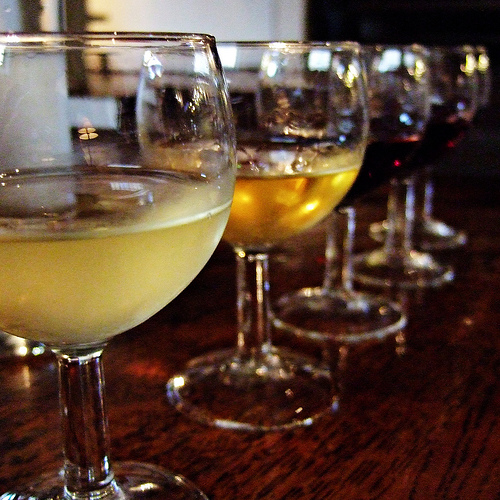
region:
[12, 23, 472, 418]
a bunch of wine glasses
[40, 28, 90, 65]
the rim of a wine glass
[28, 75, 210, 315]
the cup of a wine glass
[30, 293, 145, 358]
the base of a wine glass cup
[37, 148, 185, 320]
a bunch of light yellow wine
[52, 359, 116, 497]
the stem of a wine glass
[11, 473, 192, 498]
the base of a wine glass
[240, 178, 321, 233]
a dark yellow wine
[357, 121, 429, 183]
a dark purple wine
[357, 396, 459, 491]
a dark brown wooden tabletop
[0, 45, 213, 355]
wine glass filled with liquid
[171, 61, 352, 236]
wine glass filled with liquid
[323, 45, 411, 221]
wine glass filled with liquid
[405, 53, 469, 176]
wine glass filled with liquid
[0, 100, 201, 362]
glass is half full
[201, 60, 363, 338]
glass is half full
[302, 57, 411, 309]
glass is half full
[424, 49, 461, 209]
glass is half full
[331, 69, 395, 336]
glass of red wine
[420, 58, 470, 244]
glass of red wine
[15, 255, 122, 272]
liquid in the glass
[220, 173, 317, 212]
liquid in the glass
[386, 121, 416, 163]
liquid in the glass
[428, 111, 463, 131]
liquid in the glass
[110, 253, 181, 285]
white wine in glass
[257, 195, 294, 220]
white wine in glass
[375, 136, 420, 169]
red wine in glass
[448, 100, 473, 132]
red wine in glass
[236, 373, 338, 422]
bottom of the glass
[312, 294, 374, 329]
bottom of the glass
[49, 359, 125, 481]
stem of the wine glass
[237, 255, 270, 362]
stem of the wine glass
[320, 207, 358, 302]
stem of the wine glass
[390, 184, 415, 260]
stem of the wine glass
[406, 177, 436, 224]
stem of the wine glass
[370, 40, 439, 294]
glass of wine on the counter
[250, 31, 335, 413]
glass of wine on the counter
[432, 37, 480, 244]
glass of wine on the counter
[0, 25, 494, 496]
Row of wine glasses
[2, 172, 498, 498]
dark colored wood grain table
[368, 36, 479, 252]
Blurry wine glass on the end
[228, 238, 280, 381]
stem of a wine glass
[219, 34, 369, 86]
light reflecting off of a wine glass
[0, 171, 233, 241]
foam sitting on top of wine in a glass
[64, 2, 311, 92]
blurry window in the background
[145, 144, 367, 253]
orange liquid in a glass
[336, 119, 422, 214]
red liquid in a glass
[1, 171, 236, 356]
beige liquid in a glass